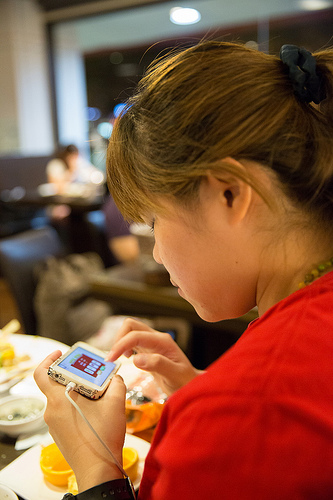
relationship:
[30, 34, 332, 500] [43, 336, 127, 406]
woman holding cellphone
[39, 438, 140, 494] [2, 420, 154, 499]
oranges on plate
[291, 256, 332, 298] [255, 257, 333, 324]
round beads on neck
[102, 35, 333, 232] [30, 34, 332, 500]
hair of woman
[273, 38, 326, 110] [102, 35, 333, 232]
scrunchie in hair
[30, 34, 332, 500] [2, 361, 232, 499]
woman at table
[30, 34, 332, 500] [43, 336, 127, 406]
woman using cellphone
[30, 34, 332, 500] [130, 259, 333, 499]
woman in shirt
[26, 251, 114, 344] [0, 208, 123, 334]
bag on a booth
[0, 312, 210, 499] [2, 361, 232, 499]
food on table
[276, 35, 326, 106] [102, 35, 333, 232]
tie on hair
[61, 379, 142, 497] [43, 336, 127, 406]
cord plugged into cellphone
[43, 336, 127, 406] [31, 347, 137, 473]
cellphone in left hand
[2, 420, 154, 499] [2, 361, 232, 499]
plate on table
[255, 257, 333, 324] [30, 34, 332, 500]
neck on woman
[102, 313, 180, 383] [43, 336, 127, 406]
fingers on cellphone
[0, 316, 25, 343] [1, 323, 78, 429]
chopstick on plate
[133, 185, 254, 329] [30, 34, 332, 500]
face of woman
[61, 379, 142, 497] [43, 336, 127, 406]
cord to cellphone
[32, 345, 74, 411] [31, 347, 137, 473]
fingers on left hand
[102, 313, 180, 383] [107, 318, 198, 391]
fingers of right hand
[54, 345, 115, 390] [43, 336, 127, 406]
screen of cellphone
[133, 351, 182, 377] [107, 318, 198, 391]
thumb on right hand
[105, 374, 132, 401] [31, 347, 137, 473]
thumb on left hand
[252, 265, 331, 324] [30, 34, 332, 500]
neck of woman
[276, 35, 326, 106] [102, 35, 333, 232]
tie in hair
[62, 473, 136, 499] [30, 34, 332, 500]
watch on woman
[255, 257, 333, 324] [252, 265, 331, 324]
neck on neck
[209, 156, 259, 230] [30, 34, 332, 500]
ear of woman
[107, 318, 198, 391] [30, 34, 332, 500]
right hand of woman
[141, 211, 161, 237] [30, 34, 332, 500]
eye of woman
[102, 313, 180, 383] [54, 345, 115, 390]
fingers tapping screen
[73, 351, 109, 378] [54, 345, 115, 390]
red square on screen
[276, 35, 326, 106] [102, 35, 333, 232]
tie holds hair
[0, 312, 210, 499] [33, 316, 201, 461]
food under hands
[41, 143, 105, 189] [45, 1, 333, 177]
person sitting by window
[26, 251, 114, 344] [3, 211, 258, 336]
bag between chair and table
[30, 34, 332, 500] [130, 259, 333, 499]
woman wearing shirt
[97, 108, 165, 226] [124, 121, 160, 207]
bangs over forehead